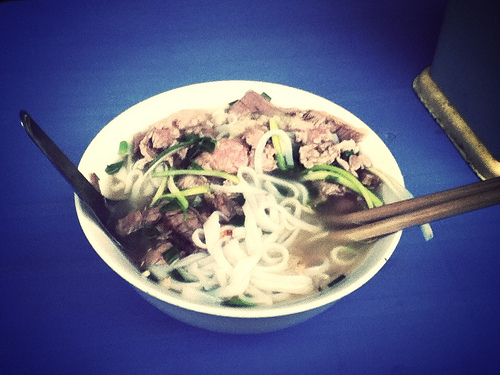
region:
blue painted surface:
[16, 68, 490, 361]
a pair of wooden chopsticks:
[321, 168, 496, 268]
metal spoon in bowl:
[23, 114, 146, 253]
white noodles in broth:
[117, 106, 389, 313]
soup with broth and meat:
[92, 83, 368, 293]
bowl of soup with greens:
[101, 123, 408, 303]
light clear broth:
[289, 218, 357, 270]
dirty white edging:
[403, 64, 497, 161]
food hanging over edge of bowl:
[381, 173, 443, 228]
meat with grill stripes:
[129, 207, 211, 256]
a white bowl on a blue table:
[6, 4, 495, 364]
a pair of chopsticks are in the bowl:
[316, 176, 498, 247]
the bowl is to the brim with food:
[103, 90, 391, 308]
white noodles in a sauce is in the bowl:
[195, 160, 350, 300]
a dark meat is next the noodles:
[117, 191, 239, 264]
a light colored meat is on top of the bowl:
[135, 95, 370, 168]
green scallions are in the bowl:
[261, 120, 396, 232]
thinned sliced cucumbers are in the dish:
[131, 152, 221, 212]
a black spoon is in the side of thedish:
[18, 107, 143, 276]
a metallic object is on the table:
[346, 71, 498, 179]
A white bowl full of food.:
[66, 77, 408, 339]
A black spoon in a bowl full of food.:
[16, 103, 158, 265]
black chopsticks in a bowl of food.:
[326, 170, 499, 241]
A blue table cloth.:
[1, 40, 496, 372]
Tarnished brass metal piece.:
[411, 63, 499, 184]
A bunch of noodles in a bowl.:
[101, 164, 353, 289]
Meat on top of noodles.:
[121, 94, 369, 195]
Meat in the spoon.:
[115, 202, 196, 262]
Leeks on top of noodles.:
[107, 142, 238, 211]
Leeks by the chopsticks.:
[297, 158, 435, 245]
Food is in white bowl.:
[68, 86, 385, 367]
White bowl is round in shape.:
[104, 79, 363, 337]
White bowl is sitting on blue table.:
[78, 67, 352, 325]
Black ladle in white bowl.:
[18, 101, 172, 300]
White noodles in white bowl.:
[218, 196, 309, 327]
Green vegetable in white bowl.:
[163, 132, 242, 269]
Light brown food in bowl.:
[158, 99, 339, 171]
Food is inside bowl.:
[46, 85, 436, 317]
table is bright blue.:
[26, 107, 489, 347]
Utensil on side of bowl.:
[326, 183, 499, 269]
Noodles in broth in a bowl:
[162, 185, 379, 333]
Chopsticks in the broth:
[318, 155, 494, 263]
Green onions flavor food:
[286, 156, 389, 210]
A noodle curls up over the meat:
[254, 128, 301, 178]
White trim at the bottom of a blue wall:
[413, 16, 491, 143]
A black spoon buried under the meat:
[15, 104, 169, 269]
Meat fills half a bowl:
[129, 103, 354, 199]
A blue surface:
[104, 14, 330, 81]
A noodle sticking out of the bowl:
[362, 165, 438, 244]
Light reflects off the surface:
[149, 30, 315, 76]